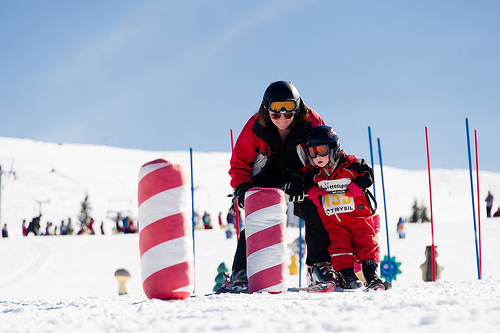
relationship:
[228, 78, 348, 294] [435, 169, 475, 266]
adult on snow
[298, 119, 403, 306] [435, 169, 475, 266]
child on snow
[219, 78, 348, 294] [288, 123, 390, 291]
adult helping child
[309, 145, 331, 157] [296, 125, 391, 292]
eyewear on child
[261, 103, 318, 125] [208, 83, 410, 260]
sunglasses on woman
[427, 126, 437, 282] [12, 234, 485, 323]
red pole in snow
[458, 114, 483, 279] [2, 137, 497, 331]
stick sticking out snow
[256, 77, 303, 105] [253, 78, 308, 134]
helmet on woman's head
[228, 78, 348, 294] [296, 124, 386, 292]
adult standing by kid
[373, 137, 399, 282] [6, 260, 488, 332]
pole sticking out of ground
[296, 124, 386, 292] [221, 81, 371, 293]
kid next to adult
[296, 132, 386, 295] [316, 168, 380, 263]
kid wearing snowsuit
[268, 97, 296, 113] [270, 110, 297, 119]
goggles above sunglasses